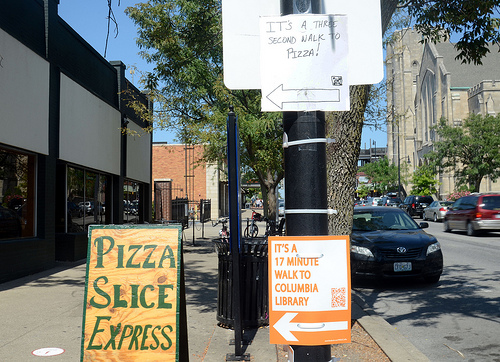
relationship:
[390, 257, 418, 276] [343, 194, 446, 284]
plate on front of car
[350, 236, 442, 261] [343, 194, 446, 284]
lights are on front of car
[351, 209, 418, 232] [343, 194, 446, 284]
glass on front of car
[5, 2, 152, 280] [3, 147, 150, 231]
building has windows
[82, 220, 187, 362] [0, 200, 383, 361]
board sitting on sidewalk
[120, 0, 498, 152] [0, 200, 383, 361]
tree lines sidewalk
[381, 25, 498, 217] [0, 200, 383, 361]
church beside sidewalk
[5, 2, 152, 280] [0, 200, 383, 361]
building beside sidewalk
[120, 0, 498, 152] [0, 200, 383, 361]
tree beside sidewalk